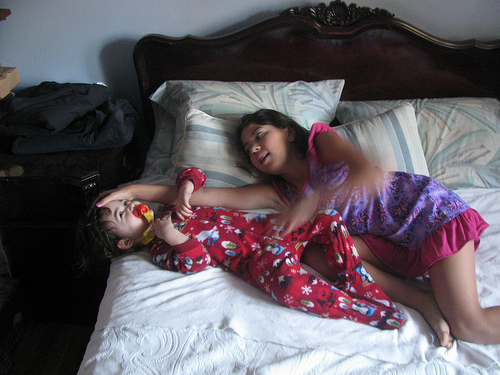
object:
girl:
[88, 108, 498, 349]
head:
[85, 196, 154, 255]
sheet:
[6, 80, 132, 153]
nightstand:
[1, 131, 129, 303]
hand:
[276, 193, 320, 237]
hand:
[87, 184, 133, 217]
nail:
[96, 202, 102, 207]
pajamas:
[148, 167, 407, 331]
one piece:
[148, 166, 407, 331]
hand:
[152, 216, 174, 239]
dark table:
[0, 147, 127, 280]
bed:
[73, 0, 500, 375]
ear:
[117, 238, 133, 249]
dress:
[268, 120, 489, 276]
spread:
[72, 183, 497, 373]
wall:
[0, 0, 499, 85]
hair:
[80, 193, 144, 258]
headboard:
[130, 0, 498, 100]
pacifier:
[134, 204, 149, 218]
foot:
[353, 298, 407, 330]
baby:
[88, 166, 406, 330]